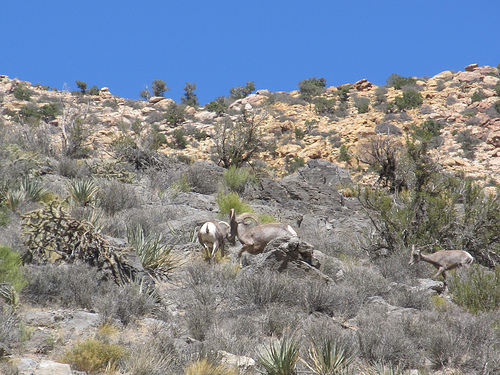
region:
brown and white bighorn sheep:
[170, 193, 247, 254]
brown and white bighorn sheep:
[257, 205, 317, 279]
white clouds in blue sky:
[11, 19, 41, 67]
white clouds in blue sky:
[62, 0, 137, 65]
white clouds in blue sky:
[181, 12, 241, 69]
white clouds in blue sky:
[231, 12, 265, 67]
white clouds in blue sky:
[288, 25, 346, 72]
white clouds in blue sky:
[341, 5, 382, 59]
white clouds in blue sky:
[387, 0, 447, 52]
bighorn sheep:
[174, 195, 239, 260]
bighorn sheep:
[231, 189, 321, 264]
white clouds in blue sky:
[18, 19, 62, 89]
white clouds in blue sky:
[135, 9, 192, 66]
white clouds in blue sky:
[172, 22, 220, 73]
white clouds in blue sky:
[208, 15, 252, 67]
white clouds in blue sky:
[260, 23, 301, 77]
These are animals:
[133, 182, 403, 302]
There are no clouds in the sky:
[154, 29, 242, 83]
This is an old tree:
[1, 200, 143, 294]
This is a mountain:
[129, 112, 222, 152]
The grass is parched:
[124, 212, 241, 327]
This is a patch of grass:
[195, 179, 227, 214]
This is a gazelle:
[393, 237, 498, 285]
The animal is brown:
[412, 236, 483, 271]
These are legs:
[427, 264, 459, 299]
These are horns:
[215, 202, 251, 230]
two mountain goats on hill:
[197, 213, 289, 283]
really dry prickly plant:
[29, 201, 115, 266]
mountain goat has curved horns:
[225, 213, 282, 223]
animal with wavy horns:
[396, 232, 481, 294]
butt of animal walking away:
[190, 225, 257, 289]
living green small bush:
[236, 178, 255, 197]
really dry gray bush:
[188, 308, 217, 333]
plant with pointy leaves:
[260, 342, 296, 372]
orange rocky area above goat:
[312, 112, 329, 145]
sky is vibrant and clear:
[178, 3, 218, 81]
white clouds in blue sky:
[82, 9, 127, 69]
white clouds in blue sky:
[157, 20, 208, 66]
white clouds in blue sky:
[238, 21, 277, 58]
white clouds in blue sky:
[371, 15, 415, 67]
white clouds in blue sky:
[448, 13, 485, 58]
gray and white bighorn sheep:
[207, 203, 311, 275]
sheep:
[179, 201, 244, 266]